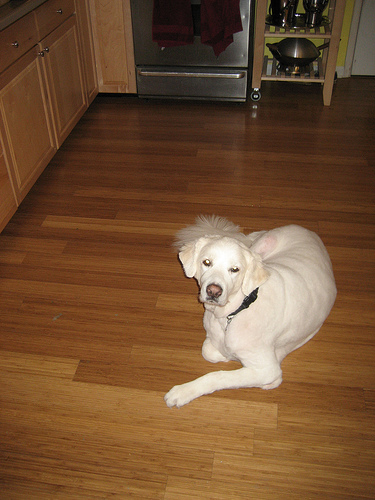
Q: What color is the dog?
A: White.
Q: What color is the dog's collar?
A: Black.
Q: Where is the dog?
A: The Kitchen.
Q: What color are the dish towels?
A: Brown.